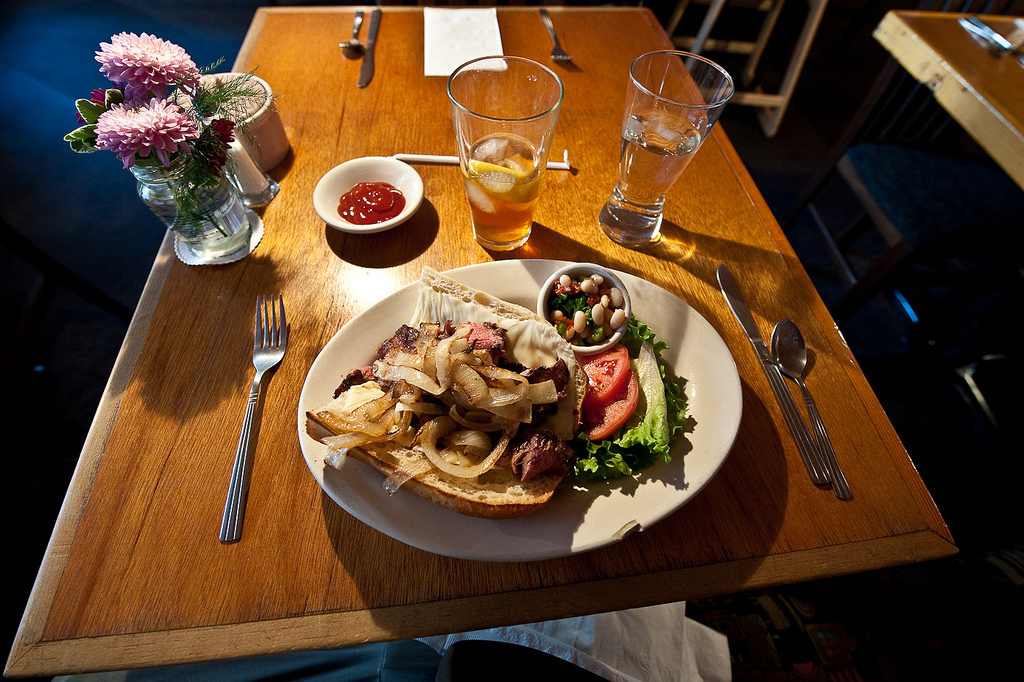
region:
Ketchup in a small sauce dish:
[314, 158, 423, 229]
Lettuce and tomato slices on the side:
[577, 337, 679, 487]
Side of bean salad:
[539, 263, 632, 350]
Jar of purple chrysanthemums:
[70, 31, 257, 266]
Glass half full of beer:
[450, 56, 561, 252]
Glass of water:
[602, 45, 732, 246]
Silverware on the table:
[713, 260, 846, 495]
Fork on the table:
[209, 294, 287, 539]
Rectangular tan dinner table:
[10, 9, 960, 680]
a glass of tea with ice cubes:
[446, 55, 561, 251]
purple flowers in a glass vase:
[59, 31, 256, 263]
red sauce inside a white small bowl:
[313, 151, 425, 229]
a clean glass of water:
[601, 46, 731, 243]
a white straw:
[393, 150, 570, 176]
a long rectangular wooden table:
[2, 9, 954, 676]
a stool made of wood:
[659, 0, 825, 136]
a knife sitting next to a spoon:
[715, 267, 852, 503]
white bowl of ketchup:
[305, 146, 432, 245]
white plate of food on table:
[290, 249, 749, 575]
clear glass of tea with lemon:
[438, 48, 572, 257]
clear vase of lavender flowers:
[56, 23, 285, 271]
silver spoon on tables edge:
[764, 310, 863, 510]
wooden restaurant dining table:
[0, 0, 965, 678]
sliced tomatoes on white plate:
[571, 342, 647, 448]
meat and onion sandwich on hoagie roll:
[296, 259, 595, 515]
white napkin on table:
[413, 1, 513, 82]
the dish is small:
[314, 154, 425, 231]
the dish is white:
[311, 152, 423, 235]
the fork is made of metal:
[219, 293, 290, 540]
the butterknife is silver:
[710, 259, 832, 487]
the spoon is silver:
[768, 313, 855, 503]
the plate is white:
[296, 258, 742, 559]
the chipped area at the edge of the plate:
[296, 260, 743, 558]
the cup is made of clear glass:
[601, 48, 734, 244]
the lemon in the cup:
[449, 56, 563, 257]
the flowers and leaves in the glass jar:
[64, 28, 280, 257]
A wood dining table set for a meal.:
[5, 5, 960, 670]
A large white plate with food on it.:
[295, 256, 739, 563]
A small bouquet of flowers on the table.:
[58, 29, 258, 251]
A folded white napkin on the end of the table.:
[418, 1, 499, 68]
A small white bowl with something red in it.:
[310, 152, 418, 228]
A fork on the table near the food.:
[213, 295, 281, 539]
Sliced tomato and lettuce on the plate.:
[573, 310, 684, 475]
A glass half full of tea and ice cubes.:
[443, 51, 561, 249]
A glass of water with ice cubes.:
[595, 45, 729, 245]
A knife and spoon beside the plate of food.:
[713, 261, 854, 496]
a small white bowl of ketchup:
[315, 158, 427, 231]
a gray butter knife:
[712, 258, 833, 496]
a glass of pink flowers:
[57, 29, 263, 257]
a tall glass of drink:
[438, 53, 566, 257]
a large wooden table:
[2, 0, 963, 679]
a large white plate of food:
[288, 250, 740, 577]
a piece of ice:
[468, 162, 520, 198]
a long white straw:
[384, 138, 575, 173]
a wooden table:
[49, 16, 950, 656]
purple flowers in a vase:
[87, 37, 261, 259]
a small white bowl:
[322, 157, 418, 228]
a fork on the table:
[217, 287, 291, 544]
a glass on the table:
[613, 51, 724, 245]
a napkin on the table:
[427, 12, 501, 71]